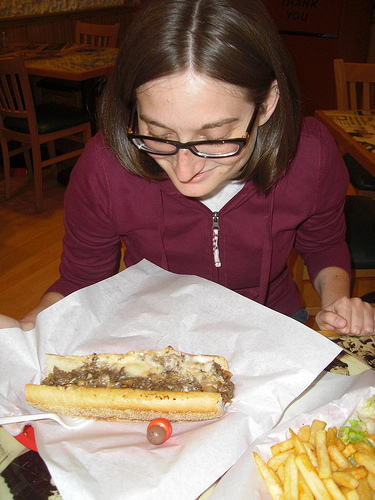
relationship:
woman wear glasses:
[3, 5, 374, 337] [121, 99, 261, 160]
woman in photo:
[3, 5, 374, 337] [2, 2, 374, 497]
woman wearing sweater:
[3, 5, 374, 337] [45, 115, 355, 316]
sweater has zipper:
[45, 115, 355, 316] [205, 209, 223, 269]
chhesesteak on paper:
[41, 345, 236, 424] [2, 259, 342, 499]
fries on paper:
[250, 422, 373, 499] [201, 370, 374, 499]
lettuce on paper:
[339, 392, 373, 446] [201, 370, 374, 499]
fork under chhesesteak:
[2, 411, 99, 433] [41, 345, 236, 424]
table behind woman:
[3, 38, 118, 85] [3, 5, 374, 337]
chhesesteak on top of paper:
[41, 345, 236, 424] [2, 259, 342, 499]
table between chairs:
[3, 38, 118, 85] [0, 20, 126, 202]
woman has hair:
[3, 5, 374, 337] [99, 1, 304, 196]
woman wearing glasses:
[3, 5, 374, 337] [121, 99, 261, 160]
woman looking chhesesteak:
[3, 5, 374, 337] [41, 345, 236, 424]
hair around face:
[99, 1, 304, 196] [132, 72, 257, 199]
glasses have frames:
[121, 99, 261, 160] [127, 108, 259, 159]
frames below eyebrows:
[127, 108, 259, 159] [134, 112, 241, 131]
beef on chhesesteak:
[45, 364, 236, 404] [41, 345, 236, 424]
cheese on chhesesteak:
[99, 345, 221, 388] [41, 345, 236, 424]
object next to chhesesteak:
[142, 417, 171, 445] [41, 345, 236, 424]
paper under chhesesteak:
[2, 259, 342, 499] [41, 345, 236, 424]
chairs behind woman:
[0, 20, 126, 202] [3, 5, 374, 337]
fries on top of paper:
[250, 422, 373, 499] [201, 370, 374, 499]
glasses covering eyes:
[121, 99, 261, 160] [145, 128, 233, 142]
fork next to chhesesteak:
[2, 411, 99, 433] [41, 345, 236, 424]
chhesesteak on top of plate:
[41, 345, 236, 424] [4, 334, 245, 464]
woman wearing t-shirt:
[3, 5, 374, 337] [195, 169, 246, 212]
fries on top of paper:
[250, 422, 373, 499] [2, 259, 342, 499]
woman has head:
[3, 5, 374, 337] [98, 3, 301, 198]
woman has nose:
[3, 5, 374, 337] [166, 136, 207, 183]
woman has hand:
[3, 5, 374, 337] [314, 294, 373, 336]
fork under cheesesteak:
[2, 411, 99, 433] [41, 345, 236, 424]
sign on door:
[281, 0, 319, 25] [269, 1, 368, 119]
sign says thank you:
[281, 0, 319, 25] [282, 1, 315, 25]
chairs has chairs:
[0, 20, 126, 202] [0, 20, 92, 214]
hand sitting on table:
[314, 294, 373, 336] [5, 336, 373, 500]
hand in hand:
[314, 294, 373, 336] [314, 294, 372, 337]